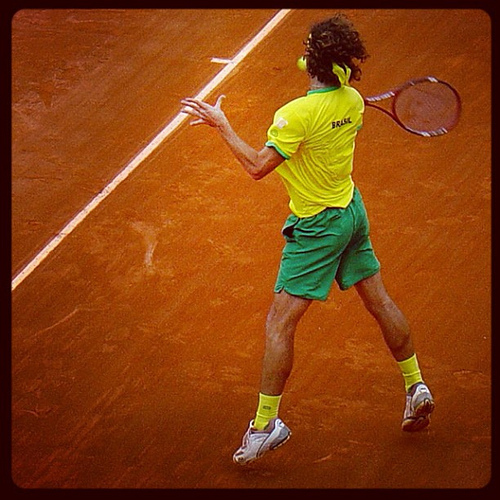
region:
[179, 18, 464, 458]
tennis player wearing gold and green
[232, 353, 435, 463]
man's gold socks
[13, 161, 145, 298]
white line painted on a tennis court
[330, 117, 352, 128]
black letters on the back of the tennis player's shirt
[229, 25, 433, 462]
tennis player wearing a gold shirt and green shorts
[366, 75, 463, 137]
white and red tennis racket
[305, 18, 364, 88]
tennis player's curly hair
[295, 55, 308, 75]
tennis ball in midair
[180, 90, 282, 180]
tennis player's outstretched left arm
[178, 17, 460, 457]
man swinging a tennis racket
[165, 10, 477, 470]
tennis player swinging at ball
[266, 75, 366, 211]
yellow shirt of tennis player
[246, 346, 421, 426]
yellow socks of tennis player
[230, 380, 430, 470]
white shoes of tennis player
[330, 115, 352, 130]
black lettering on yellow shirt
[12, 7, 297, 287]
white lines on clay tennis court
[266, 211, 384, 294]
green shorts of the tennis player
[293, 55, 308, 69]
ball player is swinging at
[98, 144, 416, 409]
footprints on the clay court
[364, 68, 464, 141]
tennis racket being swung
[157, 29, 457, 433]
player holding a racket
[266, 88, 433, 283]
the shirt is yellow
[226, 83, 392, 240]
the shirt is yellow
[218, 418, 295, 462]
Black and white sneacker.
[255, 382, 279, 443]
Yellow sock on left leg.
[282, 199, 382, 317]
Green shorts on man.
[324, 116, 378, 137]
Black letters on back of shirt.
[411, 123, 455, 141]
White stripes on racket.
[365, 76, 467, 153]
Red and white tennis racket.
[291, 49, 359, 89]
Yellow headband on head.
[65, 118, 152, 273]
White stripe in the ground.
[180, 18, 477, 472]
Man standing in the dirt.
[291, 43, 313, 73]
Yellow tennis ball in the air.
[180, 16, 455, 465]
a man leaping up while playing tennis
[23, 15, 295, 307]
the line on the tennis court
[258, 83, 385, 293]
the shirt and shorts the man is wearing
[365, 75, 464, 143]
the tennis racket in the man's hand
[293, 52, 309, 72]
the tennis ball the man is going to hit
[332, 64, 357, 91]
the back part of the headband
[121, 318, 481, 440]
the footprints on the ground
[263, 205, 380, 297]
the green shorts the man has on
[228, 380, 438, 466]
the tennis shoes the man has on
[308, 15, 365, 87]
the man's dark hair